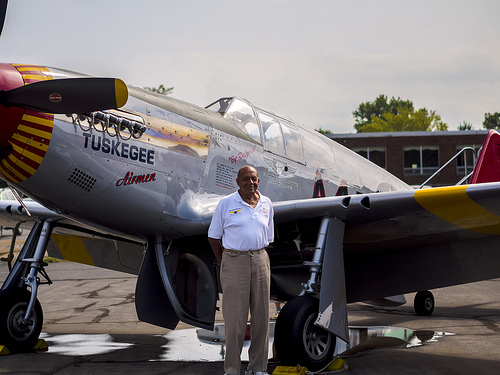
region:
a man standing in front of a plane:
[206, 165, 278, 374]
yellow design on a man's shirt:
[226, 206, 241, 215]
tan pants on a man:
[219, 246, 274, 373]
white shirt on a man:
[204, 190, 278, 253]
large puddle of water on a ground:
[36, 318, 463, 363]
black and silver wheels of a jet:
[272, 292, 339, 372]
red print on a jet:
[111, 170, 158, 189]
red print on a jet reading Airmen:
[111, 170, 161, 188]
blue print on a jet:
[74, 131, 156, 165]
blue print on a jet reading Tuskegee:
[77, 129, 157, 166]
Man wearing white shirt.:
[226, 194, 278, 252]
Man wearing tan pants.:
[224, 268, 281, 353]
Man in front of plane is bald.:
[230, 146, 252, 188]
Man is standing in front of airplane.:
[193, 302, 318, 374]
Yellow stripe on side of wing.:
[410, 183, 477, 254]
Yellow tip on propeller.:
[111, 78, 135, 105]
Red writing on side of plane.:
[120, 162, 162, 193]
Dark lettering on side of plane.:
[77, 128, 160, 161]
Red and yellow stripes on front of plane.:
[12, 54, 55, 206]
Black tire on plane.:
[275, 285, 330, 363]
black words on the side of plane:
[79, 129, 177, 164]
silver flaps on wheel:
[320, 223, 363, 346]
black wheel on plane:
[284, 295, 350, 365]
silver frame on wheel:
[291, 214, 326, 297]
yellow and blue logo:
[224, 206, 244, 220]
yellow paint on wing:
[415, 179, 476, 241]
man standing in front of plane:
[203, 157, 293, 344]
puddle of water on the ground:
[122, 325, 201, 365]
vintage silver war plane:
[41, 63, 407, 276]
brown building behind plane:
[370, 120, 456, 161]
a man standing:
[206, 163, 285, 373]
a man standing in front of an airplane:
[1, 0, 498, 374]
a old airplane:
[0, 56, 499, 373]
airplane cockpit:
[202, 91, 334, 165]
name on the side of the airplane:
[64, 116, 162, 213]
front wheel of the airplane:
[0, 208, 62, 350]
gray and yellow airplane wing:
[185, 180, 498, 325]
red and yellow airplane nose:
[0, 60, 55, 192]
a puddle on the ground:
[41, 327, 136, 359]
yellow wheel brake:
[269, 355, 358, 374]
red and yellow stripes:
[3, 108, 58, 194]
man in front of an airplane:
[164, 81, 459, 367]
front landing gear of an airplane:
[2, 205, 67, 357]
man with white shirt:
[213, 155, 278, 373]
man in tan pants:
[212, 162, 282, 373]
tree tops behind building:
[349, 83, 451, 176]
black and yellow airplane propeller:
[2, 77, 130, 119]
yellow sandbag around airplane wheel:
[267, 291, 353, 374]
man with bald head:
[210, 157, 277, 374]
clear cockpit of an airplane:
[197, 88, 352, 169]